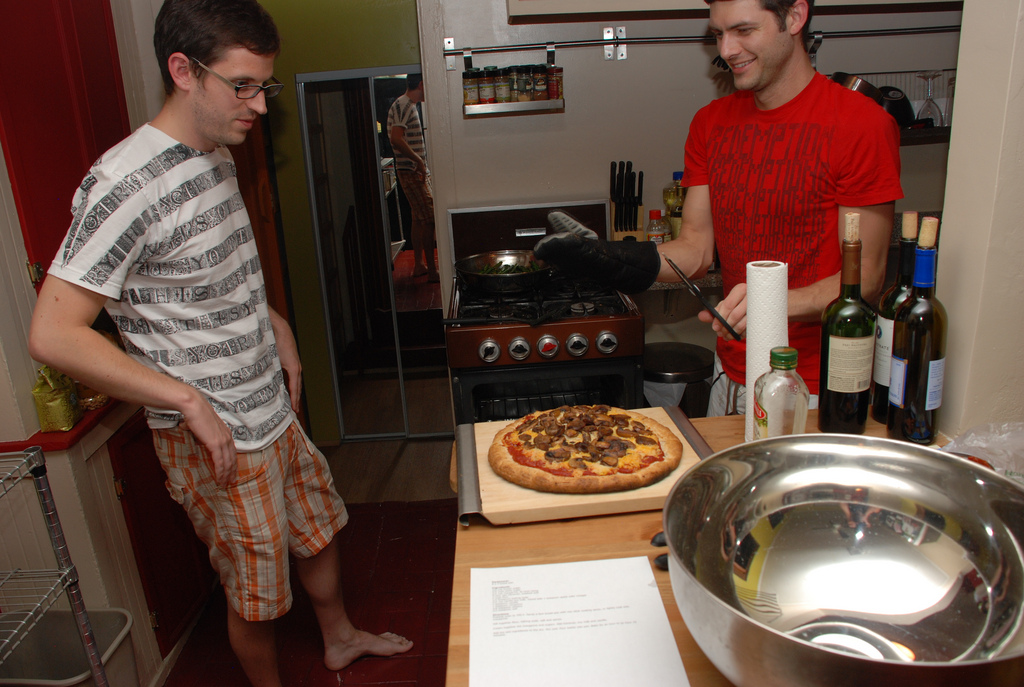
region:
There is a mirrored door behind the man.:
[291, 62, 469, 462]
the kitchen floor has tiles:
[315, 513, 418, 663]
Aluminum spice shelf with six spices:
[456, 42, 587, 122]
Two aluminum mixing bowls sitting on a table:
[658, 428, 1023, 685]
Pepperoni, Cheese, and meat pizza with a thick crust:
[443, 393, 728, 524]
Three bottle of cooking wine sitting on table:
[808, 201, 945, 445]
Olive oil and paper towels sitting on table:
[735, 250, 813, 448]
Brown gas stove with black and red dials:
[433, 200, 652, 404]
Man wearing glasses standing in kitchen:
[21, 1, 408, 670]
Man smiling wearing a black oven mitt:
[526, 1, 907, 407]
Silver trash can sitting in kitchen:
[645, 335, 716, 418]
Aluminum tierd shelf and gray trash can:
[1, 438, 137, 685]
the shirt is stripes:
[67, 142, 290, 450]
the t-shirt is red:
[672, 79, 976, 396]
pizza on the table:
[485, 395, 697, 516]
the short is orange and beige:
[147, 429, 400, 626]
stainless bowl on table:
[663, 444, 1019, 621]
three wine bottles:
[833, 193, 1011, 438]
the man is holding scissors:
[647, 246, 739, 342]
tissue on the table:
[726, 253, 818, 396]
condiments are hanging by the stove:
[451, 53, 601, 130]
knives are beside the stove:
[600, 152, 687, 261]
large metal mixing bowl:
[660, 430, 1022, 683]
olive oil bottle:
[751, 343, 808, 436]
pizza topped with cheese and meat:
[492, 397, 685, 495]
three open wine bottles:
[815, 207, 958, 442]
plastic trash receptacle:
[3, 596, 147, 683]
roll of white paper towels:
[743, 254, 795, 438]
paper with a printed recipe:
[462, 551, 696, 684]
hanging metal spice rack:
[460, 45, 581, 116]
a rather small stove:
[449, 201, 646, 413]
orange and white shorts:
[141, 406, 350, 629]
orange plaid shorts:
[144, 424, 348, 621]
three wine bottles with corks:
[818, 201, 942, 446]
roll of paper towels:
[740, 257, 794, 444]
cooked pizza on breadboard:
[486, 399, 686, 498]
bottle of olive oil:
[749, 343, 813, 439]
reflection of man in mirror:
[367, 73, 448, 295]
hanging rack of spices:
[454, 39, 566, 120]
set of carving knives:
[605, 155, 644, 242]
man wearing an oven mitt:
[519, 4, 911, 423]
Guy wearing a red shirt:
[661, 22, 912, 373]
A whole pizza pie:
[472, 371, 696, 595]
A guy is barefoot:
[224, 472, 463, 682]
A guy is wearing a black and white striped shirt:
[68, 41, 368, 536]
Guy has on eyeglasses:
[150, 18, 292, 168]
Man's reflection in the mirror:
[130, 6, 483, 339]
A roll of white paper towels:
[716, 240, 813, 419]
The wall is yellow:
[298, 12, 399, 66]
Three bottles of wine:
[831, 191, 969, 458]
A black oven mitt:
[491, 191, 721, 335]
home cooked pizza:
[489, 390, 711, 509]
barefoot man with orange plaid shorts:
[19, 5, 413, 683]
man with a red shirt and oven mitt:
[484, 1, 934, 413]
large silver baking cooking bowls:
[644, 438, 1022, 682]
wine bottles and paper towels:
[721, 191, 966, 432]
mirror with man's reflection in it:
[293, 68, 459, 446]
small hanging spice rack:
[438, 32, 600, 134]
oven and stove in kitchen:
[441, 184, 658, 410]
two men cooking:
[25, 7, 1013, 586]